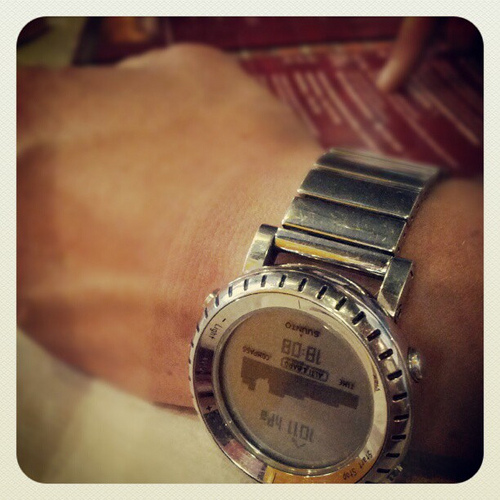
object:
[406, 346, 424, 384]
screw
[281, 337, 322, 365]
black letters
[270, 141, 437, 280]
band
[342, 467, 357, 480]
stop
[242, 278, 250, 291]
line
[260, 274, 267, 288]
line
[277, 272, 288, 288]
line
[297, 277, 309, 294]
line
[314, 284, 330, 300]
line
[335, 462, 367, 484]
tent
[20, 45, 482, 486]
table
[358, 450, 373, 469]
start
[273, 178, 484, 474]
arm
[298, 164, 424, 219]
watchlink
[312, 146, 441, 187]
watchlink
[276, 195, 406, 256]
watchlink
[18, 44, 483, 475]
skin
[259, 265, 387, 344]
silver rim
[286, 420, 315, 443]
time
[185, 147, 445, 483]
silver watch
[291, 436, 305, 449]
arrow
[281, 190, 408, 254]
link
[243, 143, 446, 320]
metallic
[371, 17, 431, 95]
finger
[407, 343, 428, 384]
knob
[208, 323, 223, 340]
word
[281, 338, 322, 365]
digits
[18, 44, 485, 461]
man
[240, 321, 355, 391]
letters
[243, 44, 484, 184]
paper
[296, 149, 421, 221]
links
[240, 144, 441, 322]
bracket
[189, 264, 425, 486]
engraving